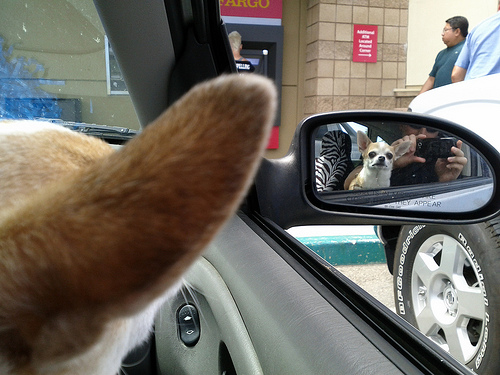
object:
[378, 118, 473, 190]
picture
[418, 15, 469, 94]
man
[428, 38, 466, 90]
shirt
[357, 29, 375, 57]
lettering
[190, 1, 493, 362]
window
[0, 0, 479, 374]
car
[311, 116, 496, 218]
mirror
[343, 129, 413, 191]
dog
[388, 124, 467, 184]
person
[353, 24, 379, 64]
sign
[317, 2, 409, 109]
wall